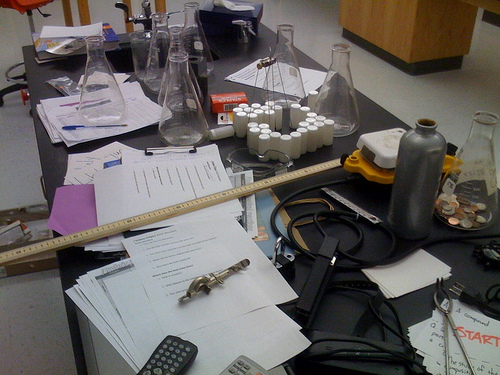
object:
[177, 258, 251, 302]
compass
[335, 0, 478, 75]
desk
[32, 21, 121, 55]
textbook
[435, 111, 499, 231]
beaker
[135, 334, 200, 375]
calculator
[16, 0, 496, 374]
desk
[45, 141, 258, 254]
paper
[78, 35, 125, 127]
beakers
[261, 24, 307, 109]
beakers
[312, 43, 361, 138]
beakers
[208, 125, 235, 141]
bottle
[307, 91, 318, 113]
bottle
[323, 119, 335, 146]
bottle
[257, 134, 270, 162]
bottle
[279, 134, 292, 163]
bottle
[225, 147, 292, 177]
glasses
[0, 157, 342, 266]
ruler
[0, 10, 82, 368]
floor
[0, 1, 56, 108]
chair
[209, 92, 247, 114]
red box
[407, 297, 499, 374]
paper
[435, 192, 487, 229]
coins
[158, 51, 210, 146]
beaker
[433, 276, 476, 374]
tongs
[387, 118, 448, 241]
bottle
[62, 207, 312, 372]
papers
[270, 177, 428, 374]
cable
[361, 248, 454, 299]
papers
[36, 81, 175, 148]
papers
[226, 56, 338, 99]
papers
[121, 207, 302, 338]
paper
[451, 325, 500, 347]
red ink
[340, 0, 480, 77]
bottom